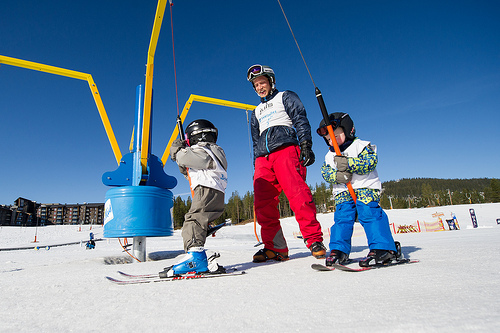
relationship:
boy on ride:
[166, 119, 229, 280] [28, 42, 341, 257]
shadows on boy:
[224, 238, 419, 273] [317, 112, 403, 266]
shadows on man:
[224, 238, 419, 273] [243, 63, 326, 261]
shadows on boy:
[224, 238, 419, 273] [166, 119, 229, 280]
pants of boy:
[176, 172, 221, 242] [166, 119, 229, 280]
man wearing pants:
[243, 63, 326, 261] [249, 141, 330, 246]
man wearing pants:
[243, 63, 326, 261] [245, 133, 305, 237]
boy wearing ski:
[317, 112, 403, 266] [334, 259, 418, 272]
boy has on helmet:
[317, 112, 403, 266] [318, 110, 357, 149]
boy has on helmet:
[166, 119, 229, 280] [186, 115, 218, 142]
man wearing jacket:
[243, 63, 326, 261] [234, 91, 319, 151]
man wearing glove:
[243, 63, 326, 261] [295, 133, 320, 170]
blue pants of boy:
[330, 200, 400, 258] [317, 112, 403, 266]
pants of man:
[249, 141, 330, 246] [243, 63, 326, 261]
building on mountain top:
[0, 196, 104, 227] [3, 202, 499, 323]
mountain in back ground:
[384, 169, 497, 199] [93, 99, 485, 219]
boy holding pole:
[317, 112, 403, 266] [314, 89, 359, 203]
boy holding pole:
[166, 119, 229, 280] [161, 3, 201, 201]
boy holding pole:
[166, 119, 229, 280] [314, 89, 359, 203]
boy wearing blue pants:
[317, 112, 403, 266] [331, 188, 398, 253]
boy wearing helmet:
[166, 119, 229, 280] [182, 117, 220, 147]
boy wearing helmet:
[317, 112, 403, 266] [318, 110, 357, 149]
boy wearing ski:
[166, 119, 229, 280] [115, 268, 166, 281]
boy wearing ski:
[166, 119, 229, 280] [105, 266, 245, 289]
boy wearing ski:
[317, 112, 403, 266] [311, 256, 359, 274]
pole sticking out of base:
[0, 54, 124, 166] [102, 84, 177, 261]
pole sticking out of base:
[140, 0, 170, 170] [102, 84, 177, 261]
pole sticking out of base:
[161, 94, 257, 162] [102, 84, 177, 261]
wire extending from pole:
[165, 4, 180, 122] [176, 115, 193, 200]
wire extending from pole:
[275, 3, 318, 92] [314, 89, 359, 203]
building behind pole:
[10, 196, 104, 227] [0, 54, 124, 166]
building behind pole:
[10, 196, 104, 227] [161, 3, 201, 201]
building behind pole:
[10, 196, 104, 227] [161, 94, 257, 162]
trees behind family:
[165, 192, 429, 220] [171, 61, 407, 271]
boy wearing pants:
[317, 112, 403, 266] [319, 187, 394, 264]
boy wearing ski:
[317, 112, 403, 266] [335, 239, 418, 275]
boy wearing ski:
[317, 112, 403, 266] [313, 253, 368, 272]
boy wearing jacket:
[317, 112, 403, 266] [322, 143, 389, 210]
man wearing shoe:
[243, 63, 326, 261] [252, 245, 288, 263]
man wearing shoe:
[243, 63, 326, 261] [309, 240, 325, 257]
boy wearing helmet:
[166, 119, 229, 280] [182, 112, 218, 144]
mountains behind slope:
[376, 153, 497, 223] [0, 201, 498, 331]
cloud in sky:
[0, 92, 500, 191] [0, 0, 499, 205]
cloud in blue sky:
[0, 92, 500, 191] [2, 1, 497, 210]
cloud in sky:
[0, 134, 497, 202] [0, 0, 499, 205]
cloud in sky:
[0, 92, 500, 191] [2, 0, 497, 179]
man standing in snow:
[243, 63, 326, 261] [2, 199, 498, 328]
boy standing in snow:
[317, 112, 403, 266] [2, 199, 498, 328]